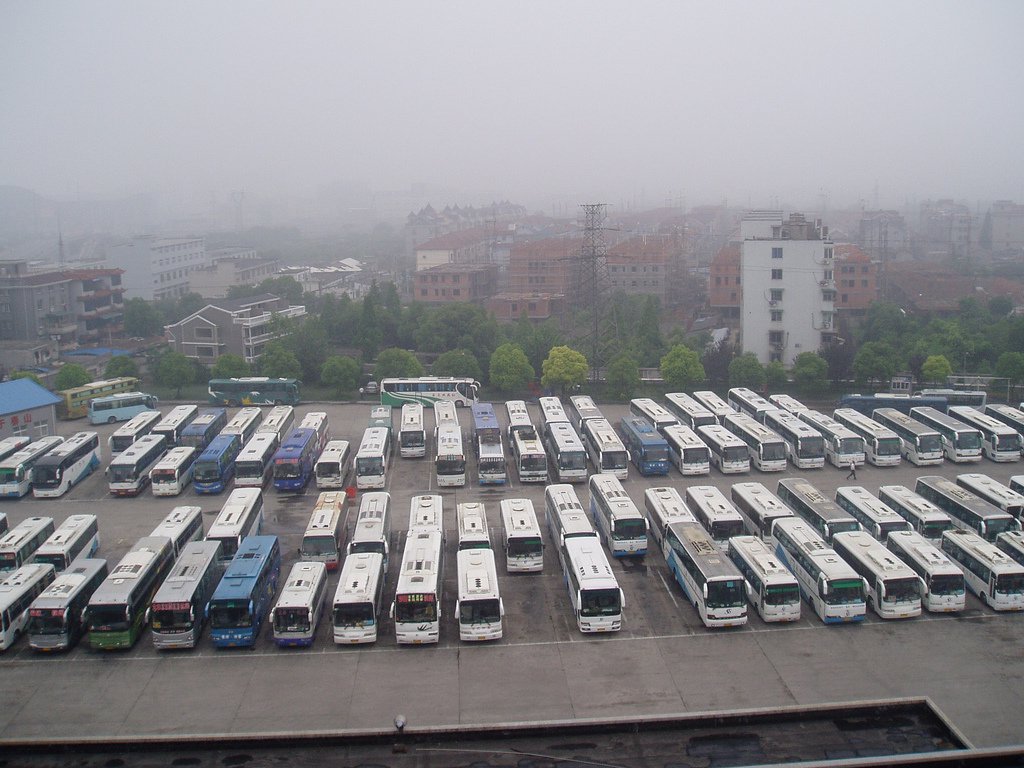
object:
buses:
[17, 382, 1022, 673]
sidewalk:
[14, 619, 950, 729]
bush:
[348, 267, 417, 363]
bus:
[455, 544, 509, 648]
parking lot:
[2, 397, 1024, 761]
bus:
[558, 526, 630, 637]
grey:
[30, 206, 994, 224]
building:
[715, 201, 852, 396]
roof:
[13, 370, 29, 409]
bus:
[200, 526, 287, 645]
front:
[203, 597, 257, 649]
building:
[161, 305, 248, 385]